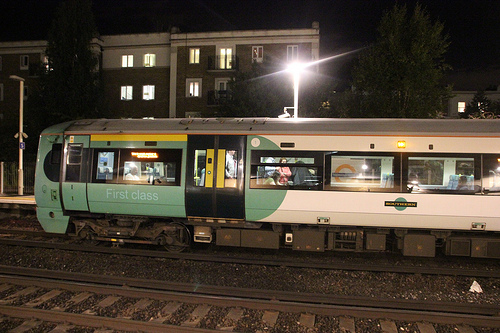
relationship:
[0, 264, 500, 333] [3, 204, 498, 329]
track in gravel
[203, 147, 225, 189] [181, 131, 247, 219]
strip on door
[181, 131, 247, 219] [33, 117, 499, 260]
door on bus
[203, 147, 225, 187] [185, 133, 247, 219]
strip on door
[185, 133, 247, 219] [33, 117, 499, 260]
door on bus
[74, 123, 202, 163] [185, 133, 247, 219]
strip on door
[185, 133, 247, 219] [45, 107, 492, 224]
door on bus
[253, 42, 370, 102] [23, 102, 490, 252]
bright light behind train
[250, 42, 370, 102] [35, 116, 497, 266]
bright light behind train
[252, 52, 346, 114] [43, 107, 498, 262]
light behind train.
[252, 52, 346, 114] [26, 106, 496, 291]
light behind train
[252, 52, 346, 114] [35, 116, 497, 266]
light behind train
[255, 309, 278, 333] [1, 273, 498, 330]
cross tie on track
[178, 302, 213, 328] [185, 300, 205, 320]
cross tie on track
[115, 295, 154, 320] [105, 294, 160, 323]
cross tie on track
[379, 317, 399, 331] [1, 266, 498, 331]
cross tie on track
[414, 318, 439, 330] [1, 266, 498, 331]
cross tie on track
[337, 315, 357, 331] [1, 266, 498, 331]
cross tie on track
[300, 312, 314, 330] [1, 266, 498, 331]
cross tie on track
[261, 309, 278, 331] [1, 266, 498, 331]
cross tie on track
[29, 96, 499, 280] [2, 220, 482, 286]
train going down track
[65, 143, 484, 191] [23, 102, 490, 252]
windows on train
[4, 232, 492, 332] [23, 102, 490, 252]
track next to train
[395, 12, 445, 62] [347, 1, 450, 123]
leaves on tree